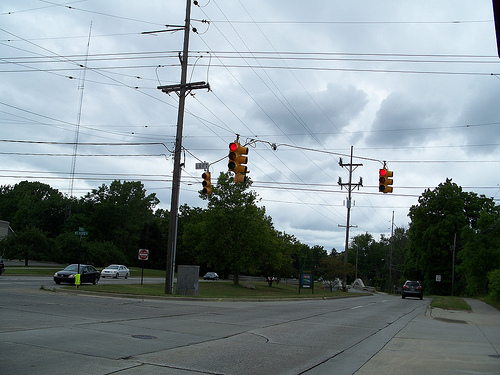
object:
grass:
[60, 280, 373, 299]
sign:
[298, 264, 314, 294]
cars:
[203, 272, 219, 281]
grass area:
[377, 288, 500, 312]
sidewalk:
[352, 291, 500, 375]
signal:
[378, 168, 387, 191]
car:
[53, 264, 100, 285]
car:
[101, 265, 131, 279]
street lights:
[202, 172, 212, 194]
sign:
[138, 249, 150, 285]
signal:
[228, 142, 237, 169]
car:
[400, 280, 423, 299]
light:
[378, 169, 394, 193]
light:
[228, 139, 250, 182]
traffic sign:
[435, 275, 441, 282]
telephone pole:
[341, 146, 355, 291]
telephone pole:
[164, 0, 193, 294]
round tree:
[0, 223, 50, 266]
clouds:
[1, 2, 497, 255]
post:
[141, 260, 144, 286]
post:
[77, 238, 82, 288]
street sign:
[75, 227, 89, 236]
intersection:
[0, 276, 500, 375]